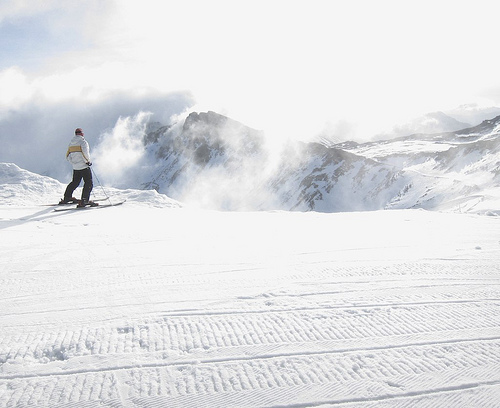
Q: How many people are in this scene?
A: One.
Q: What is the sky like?
A: Cloudy.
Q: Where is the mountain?
A: In the distance.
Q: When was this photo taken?
A: Daytime.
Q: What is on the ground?
A: Snow.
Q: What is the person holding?
A: Ski poles.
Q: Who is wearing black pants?
A: The person.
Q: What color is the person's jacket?
A: White.